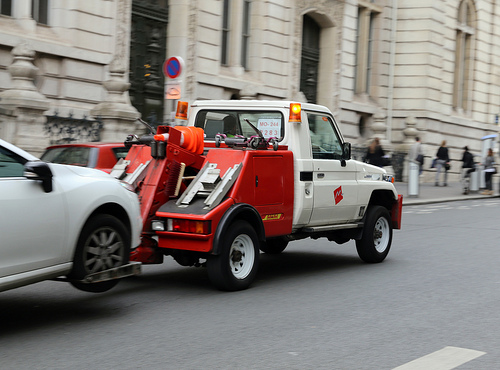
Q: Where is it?
A: This is at the street.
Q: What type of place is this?
A: It is a street.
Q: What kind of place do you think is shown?
A: It is a street.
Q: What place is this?
A: It is a street.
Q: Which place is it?
A: It is a street.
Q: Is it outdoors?
A: Yes, it is outdoors.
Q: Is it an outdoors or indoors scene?
A: It is outdoors.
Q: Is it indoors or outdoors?
A: It is outdoors.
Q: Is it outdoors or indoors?
A: It is outdoors.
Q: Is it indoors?
A: No, it is outdoors.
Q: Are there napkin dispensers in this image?
A: No, there are no napkin dispensers.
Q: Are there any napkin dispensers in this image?
A: No, there are no napkin dispensers.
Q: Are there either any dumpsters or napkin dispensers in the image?
A: No, there are no napkin dispensers or dumpsters.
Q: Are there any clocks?
A: No, there are no clocks.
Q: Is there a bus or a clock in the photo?
A: No, there are no clocks or buses.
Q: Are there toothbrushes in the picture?
A: No, there are no toothbrushes.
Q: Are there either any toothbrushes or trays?
A: No, there are no toothbrushes or trays.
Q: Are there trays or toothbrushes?
A: No, there are no toothbrushes or trays.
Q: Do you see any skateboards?
A: No, there are no skateboards.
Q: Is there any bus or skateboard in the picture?
A: No, there are no skateboards or buses.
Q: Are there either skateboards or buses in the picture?
A: No, there are no skateboards or buses.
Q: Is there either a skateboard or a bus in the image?
A: No, there are no skateboards or buses.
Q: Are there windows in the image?
A: Yes, there is a window.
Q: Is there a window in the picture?
A: Yes, there is a window.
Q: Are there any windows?
A: Yes, there is a window.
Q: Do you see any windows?
A: Yes, there is a window.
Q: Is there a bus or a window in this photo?
A: Yes, there is a window.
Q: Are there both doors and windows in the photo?
A: Yes, there are both a window and a door.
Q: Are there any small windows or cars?
A: Yes, there is a small window.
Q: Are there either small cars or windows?
A: Yes, there is a small window.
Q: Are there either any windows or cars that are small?
A: Yes, the window is small.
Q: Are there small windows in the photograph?
A: Yes, there is a small window.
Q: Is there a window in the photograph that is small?
A: Yes, there is a small window.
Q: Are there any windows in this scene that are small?
A: Yes, there is a window that is small.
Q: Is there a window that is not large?
A: Yes, there is a small window.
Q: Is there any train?
A: No, there are no trains.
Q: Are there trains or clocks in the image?
A: No, there are no trains or clocks.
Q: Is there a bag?
A: No, there are no bags.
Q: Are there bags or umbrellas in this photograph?
A: No, there are no bags or umbrellas.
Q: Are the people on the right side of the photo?
A: Yes, the people are on the right of the image.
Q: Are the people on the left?
A: No, the people are on the right of the image.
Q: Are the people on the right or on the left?
A: The people are on the right of the image.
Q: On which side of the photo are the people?
A: The people are on the right of the image.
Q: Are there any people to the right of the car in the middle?
A: Yes, there are people to the right of the car.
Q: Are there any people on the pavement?
A: Yes, there are people on the pavement.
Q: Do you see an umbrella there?
A: No, there are no umbrellas.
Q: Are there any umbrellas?
A: No, there are no umbrellas.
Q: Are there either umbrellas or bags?
A: No, there are no umbrellas or bags.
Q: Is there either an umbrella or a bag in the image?
A: No, there are no umbrellas or bags.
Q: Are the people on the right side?
A: Yes, the people are on the right of the image.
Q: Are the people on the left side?
A: No, the people are on the right of the image.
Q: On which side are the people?
A: The people are on the right of the image.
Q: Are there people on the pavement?
A: Yes, there are people on the pavement.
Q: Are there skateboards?
A: No, there are no skateboards.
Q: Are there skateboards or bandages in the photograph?
A: No, there are no skateboards or bandages.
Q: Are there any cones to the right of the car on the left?
A: Yes, there are cones to the right of the car.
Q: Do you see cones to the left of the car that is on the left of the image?
A: No, the cones are to the right of the car.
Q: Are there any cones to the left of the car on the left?
A: No, the cones are to the right of the car.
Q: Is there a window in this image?
A: Yes, there is a window.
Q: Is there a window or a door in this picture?
A: Yes, there is a window.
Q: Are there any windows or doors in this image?
A: Yes, there is a window.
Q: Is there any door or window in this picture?
A: Yes, there is a window.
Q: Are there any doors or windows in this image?
A: Yes, there is a window.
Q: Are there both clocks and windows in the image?
A: No, there is a window but no clocks.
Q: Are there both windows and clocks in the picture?
A: No, there is a window but no clocks.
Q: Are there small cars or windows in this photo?
A: Yes, there is a small window.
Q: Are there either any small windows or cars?
A: Yes, there is a small window.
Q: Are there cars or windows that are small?
A: Yes, the window is small.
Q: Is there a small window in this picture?
A: Yes, there is a small window.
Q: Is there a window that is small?
A: Yes, there is a window that is small.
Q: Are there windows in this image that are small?
A: Yes, there is a window that is small.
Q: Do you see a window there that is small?
A: Yes, there is a window that is small.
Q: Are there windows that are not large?
A: Yes, there is a small window.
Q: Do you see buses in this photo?
A: No, there are no buses.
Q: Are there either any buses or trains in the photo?
A: No, there are no buses or trains.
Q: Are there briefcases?
A: No, there are no briefcases.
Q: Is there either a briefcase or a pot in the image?
A: No, there are no briefcases or pots.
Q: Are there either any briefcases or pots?
A: No, there are no briefcases or pots.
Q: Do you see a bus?
A: No, there are no buses.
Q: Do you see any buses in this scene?
A: No, there are no buses.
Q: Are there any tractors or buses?
A: No, there are no buses or tractors.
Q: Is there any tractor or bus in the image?
A: No, there are no buses or tractors.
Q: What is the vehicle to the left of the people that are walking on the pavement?
A: The vehicle is a car.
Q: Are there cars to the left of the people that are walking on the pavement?
A: Yes, there is a car to the left of the people.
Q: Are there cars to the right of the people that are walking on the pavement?
A: No, the car is to the left of the people.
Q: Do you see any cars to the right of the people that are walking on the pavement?
A: No, the car is to the left of the people.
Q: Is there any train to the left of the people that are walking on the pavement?
A: No, there is a car to the left of the people.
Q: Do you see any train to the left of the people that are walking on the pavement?
A: No, there is a car to the left of the people.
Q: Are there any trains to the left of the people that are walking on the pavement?
A: No, there is a car to the left of the people.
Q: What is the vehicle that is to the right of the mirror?
A: The vehicle is a car.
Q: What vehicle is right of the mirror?
A: The vehicle is a car.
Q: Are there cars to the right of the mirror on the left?
A: Yes, there is a car to the right of the mirror.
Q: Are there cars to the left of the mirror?
A: No, the car is to the right of the mirror.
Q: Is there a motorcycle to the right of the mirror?
A: No, there is a car to the right of the mirror.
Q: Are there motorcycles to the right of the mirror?
A: No, there is a car to the right of the mirror.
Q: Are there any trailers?
A: No, there are no trailers.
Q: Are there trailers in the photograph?
A: No, there are no trailers.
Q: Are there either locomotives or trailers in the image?
A: No, there are no trailers or locomotives.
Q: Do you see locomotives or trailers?
A: No, there are no trailers or locomotives.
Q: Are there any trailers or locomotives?
A: No, there are no trailers or locomotives.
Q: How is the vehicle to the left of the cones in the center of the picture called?
A: The vehicle is a car.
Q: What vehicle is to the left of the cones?
A: The vehicle is a car.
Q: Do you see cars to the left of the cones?
A: Yes, there is a car to the left of the cones.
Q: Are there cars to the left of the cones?
A: Yes, there is a car to the left of the cones.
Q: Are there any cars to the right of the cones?
A: No, the car is to the left of the cones.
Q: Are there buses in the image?
A: No, there are no buses.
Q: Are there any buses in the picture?
A: No, there are no buses.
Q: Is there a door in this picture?
A: Yes, there is a door.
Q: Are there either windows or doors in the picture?
A: Yes, there is a door.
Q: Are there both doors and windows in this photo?
A: Yes, there are both a door and a window.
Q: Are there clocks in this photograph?
A: No, there are no clocks.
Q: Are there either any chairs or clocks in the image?
A: No, there are no clocks or chairs.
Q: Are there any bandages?
A: No, there are no bandages.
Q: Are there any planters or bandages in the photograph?
A: No, there are no bandages or planters.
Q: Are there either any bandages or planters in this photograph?
A: No, there are no bandages or planters.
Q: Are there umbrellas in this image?
A: No, there are no umbrellas.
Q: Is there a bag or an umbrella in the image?
A: No, there are no umbrellas or bags.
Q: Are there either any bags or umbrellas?
A: No, there are no umbrellas or bags.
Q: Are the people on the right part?
A: Yes, the people are on the right of the image.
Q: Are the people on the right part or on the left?
A: The people are on the right of the image.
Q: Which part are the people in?
A: The people are on the right of the image.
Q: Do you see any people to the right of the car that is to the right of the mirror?
A: Yes, there are people to the right of the car.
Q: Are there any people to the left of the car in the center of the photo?
A: No, the people are to the right of the car.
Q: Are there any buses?
A: No, there are no buses.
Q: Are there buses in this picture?
A: No, there are no buses.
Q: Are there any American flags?
A: No, there are no American flags.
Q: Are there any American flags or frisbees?
A: No, there are no American flags or frisbees.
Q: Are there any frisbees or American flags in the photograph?
A: No, there are no American flags or frisbees.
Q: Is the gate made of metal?
A: Yes, the gate is made of metal.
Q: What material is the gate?
A: The gate is made of metal.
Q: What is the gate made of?
A: The gate is made of metal.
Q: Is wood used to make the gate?
A: No, the gate is made of metal.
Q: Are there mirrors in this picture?
A: Yes, there is a mirror.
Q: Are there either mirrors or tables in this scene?
A: Yes, there is a mirror.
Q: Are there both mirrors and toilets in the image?
A: No, there is a mirror but no toilets.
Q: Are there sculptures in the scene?
A: No, there are no sculptures.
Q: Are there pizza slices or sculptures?
A: No, there are no sculptures or pizza slices.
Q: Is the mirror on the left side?
A: Yes, the mirror is on the left of the image.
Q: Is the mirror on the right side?
A: No, the mirror is on the left of the image.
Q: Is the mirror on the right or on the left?
A: The mirror is on the left of the image.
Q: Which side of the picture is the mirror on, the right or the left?
A: The mirror is on the left of the image.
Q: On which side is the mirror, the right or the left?
A: The mirror is on the left of the image.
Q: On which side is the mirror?
A: The mirror is on the left of the image.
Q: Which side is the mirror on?
A: The mirror is on the left of the image.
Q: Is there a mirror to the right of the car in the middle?
A: No, the mirror is to the left of the car.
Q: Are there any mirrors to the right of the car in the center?
A: No, the mirror is to the left of the car.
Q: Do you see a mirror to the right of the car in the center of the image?
A: No, the mirror is to the left of the car.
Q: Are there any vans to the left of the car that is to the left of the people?
A: No, there is a mirror to the left of the car.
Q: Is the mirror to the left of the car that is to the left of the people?
A: Yes, the mirror is to the left of the car.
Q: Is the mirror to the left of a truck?
A: No, the mirror is to the left of the car.